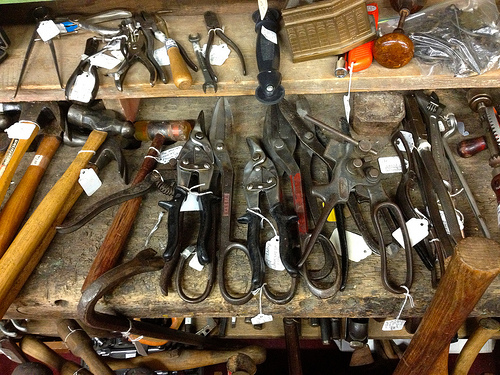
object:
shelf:
[0, 316, 500, 347]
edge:
[83, 320, 415, 352]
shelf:
[0, 8, 499, 107]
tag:
[391, 218, 428, 251]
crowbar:
[73, 245, 239, 351]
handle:
[1, 123, 38, 202]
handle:
[301, 230, 345, 299]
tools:
[454, 133, 490, 160]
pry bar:
[78, 246, 246, 353]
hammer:
[81, 118, 194, 296]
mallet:
[79, 133, 168, 290]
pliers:
[198, 10, 248, 83]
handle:
[157, 190, 184, 261]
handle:
[196, 192, 222, 264]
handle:
[237, 211, 268, 286]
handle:
[272, 204, 301, 276]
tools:
[444, 317, 497, 375]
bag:
[372, 0, 499, 80]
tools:
[338, 45, 372, 80]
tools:
[302, 113, 381, 159]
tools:
[278, 97, 400, 280]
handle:
[403, 238, 500, 373]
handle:
[251, 4, 283, 104]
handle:
[56, 320, 108, 374]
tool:
[163, 107, 218, 264]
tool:
[186, 31, 217, 92]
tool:
[63, 31, 99, 105]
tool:
[240, 134, 304, 287]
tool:
[11, 6, 65, 97]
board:
[0, 89, 497, 317]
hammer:
[0, 105, 135, 304]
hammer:
[0, 103, 61, 208]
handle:
[0, 130, 111, 299]